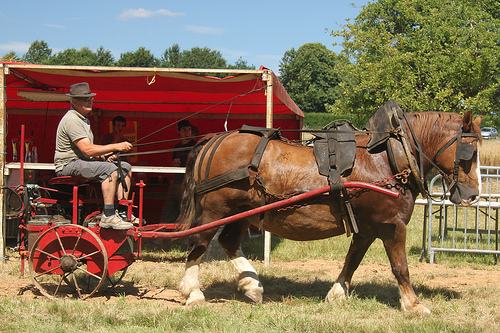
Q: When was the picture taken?
A: Daytime.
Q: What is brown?
A: Horse.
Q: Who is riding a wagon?
A: A man.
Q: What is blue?
A: Sky.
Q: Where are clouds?
A: In the sky.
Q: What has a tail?
A: A horse.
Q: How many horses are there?
A: One.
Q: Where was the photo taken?
A: On a farm.